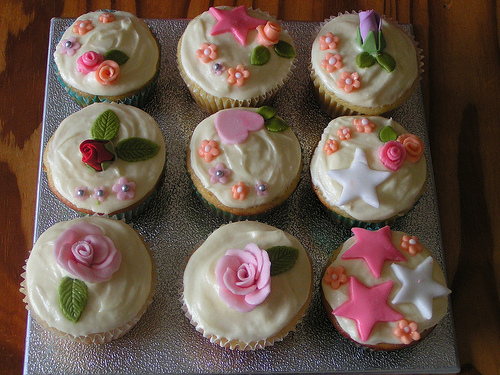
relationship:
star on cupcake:
[327, 147, 394, 207] [311, 117, 427, 228]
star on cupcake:
[341, 226, 409, 277] [322, 226, 452, 350]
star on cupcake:
[210, 5, 270, 44] [176, 4, 297, 117]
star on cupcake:
[391, 255, 452, 319] [322, 226, 452, 350]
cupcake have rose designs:
[20, 210, 157, 344] [52, 220, 300, 324]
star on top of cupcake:
[341, 226, 409, 277] [322, 226, 452, 350]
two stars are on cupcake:
[333, 225, 407, 340] [322, 226, 452, 350]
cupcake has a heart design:
[189, 107, 306, 218] [216, 109, 267, 144]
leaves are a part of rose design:
[92, 109, 161, 162] [79, 138, 117, 172]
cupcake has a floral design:
[309, 10, 425, 119] [319, 32, 360, 92]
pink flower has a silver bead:
[60, 36, 80, 55] [65, 41, 72, 48]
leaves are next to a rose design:
[92, 109, 161, 162] [79, 138, 117, 172]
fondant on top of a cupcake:
[333, 275, 403, 342] [322, 226, 452, 350]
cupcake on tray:
[322, 226, 452, 350] [24, 17, 462, 374]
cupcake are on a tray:
[20, 210, 157, 344] [24, 17, 462, 374]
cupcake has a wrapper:
[54, 10, 161, 111] [53, 13, 162, 111]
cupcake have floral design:
[20, 210, 157, 344] [52, 220, 300, 324]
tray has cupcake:
[24, 17, 462, 374] [20, 210, 157, 344]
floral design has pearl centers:
[319, 32, 360, 92] [326, 35, 353, 83]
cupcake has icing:
[43, 100, 169, 224] [49, 102, 166, 212]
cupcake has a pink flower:
[20, 210, 157, 344] [56, 223, 123, 284]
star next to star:
[333, 275, 403, 342] [389, 253, 450, 324]